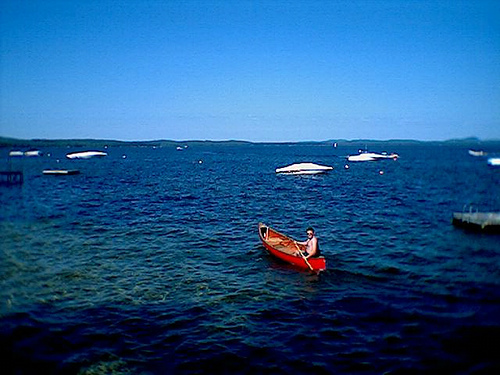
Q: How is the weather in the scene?
A: It is clear.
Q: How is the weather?
A: It is clear.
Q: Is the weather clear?
A: Yes, it is clear.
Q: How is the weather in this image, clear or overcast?
A: It is clear.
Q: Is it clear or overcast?
A: It is clear.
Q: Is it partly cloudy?
A: No, it is clear.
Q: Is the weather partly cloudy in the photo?
A: No, it is clear.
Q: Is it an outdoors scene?
A: Yes, it is outdoors.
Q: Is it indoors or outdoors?
A: It is outdoors.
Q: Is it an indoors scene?
A: No, it is outdoors.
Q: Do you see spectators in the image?
A: No, there are no spectators.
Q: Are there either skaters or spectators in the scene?
A: No, there are no spectators or skaters.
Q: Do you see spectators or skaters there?
A: No, there are no spectators or skaters.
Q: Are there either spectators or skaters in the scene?
A: No, there are no spectators or skaters.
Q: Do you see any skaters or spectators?
A: No, there are no spectators or skaters.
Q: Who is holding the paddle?
A: The man is holding the paddle.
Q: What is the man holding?
A: The man is holding the oar.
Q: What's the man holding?
A: The man is holding the oar.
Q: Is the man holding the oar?
A: Yes, the man is holding the oar.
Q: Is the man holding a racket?
A: No, the man is holding the oar.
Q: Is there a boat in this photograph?
A: Yes, there is a boat.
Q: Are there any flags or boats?
A: Yes, there is a boat.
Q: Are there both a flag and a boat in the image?
A: No, there is a boat but no flags.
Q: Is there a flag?
A: No, there are no flags.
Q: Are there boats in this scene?
A: Yes, there is a boat.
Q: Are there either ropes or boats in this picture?
A: Yes, there is a boat.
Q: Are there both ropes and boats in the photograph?
A: No, there is a boat but no ropes.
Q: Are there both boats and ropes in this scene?
A: No, there is a boat but no ropes.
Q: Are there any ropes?
A: No, there are no ropes.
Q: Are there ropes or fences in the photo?
A: No, there are no ropes or fences.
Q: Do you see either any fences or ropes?
A: No, there are no ropes or fences.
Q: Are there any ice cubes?
A: No, there are no ice cubes.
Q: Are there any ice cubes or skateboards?
A: No, there are no ice cubes or skateboards.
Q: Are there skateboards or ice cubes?
A: No, there are no ice cubes or skateboards.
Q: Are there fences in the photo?
A: No, there are no fences.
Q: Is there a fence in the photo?
A: No, there are no fences.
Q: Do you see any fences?
A: No, there are no fences.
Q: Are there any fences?
A: No, there are no fences.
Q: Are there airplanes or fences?
A: No, there are no fences or airplanes.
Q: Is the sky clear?
A: Yes, the sky is clear.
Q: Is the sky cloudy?
A: No, the sky is clear.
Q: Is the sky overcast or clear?
A: The sky is clear.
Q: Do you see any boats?
A: Yes, there is a boat.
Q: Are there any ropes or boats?
A: Yes, there is a boat.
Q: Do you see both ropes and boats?
A: No, there is a boat but no ropes.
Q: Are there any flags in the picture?
A: No, there are no flags.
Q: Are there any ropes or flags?
A: No, there are no flags or ropes.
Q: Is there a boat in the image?
A: Yes, there is a boat.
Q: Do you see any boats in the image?
A: Yes, there is a boat.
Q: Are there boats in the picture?
A: Yes, there is a boat.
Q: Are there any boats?
A: Yes, there is a boat.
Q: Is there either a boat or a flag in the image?
A: Yes, there is a boat.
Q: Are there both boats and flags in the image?
A: No, there is a boat but no flags.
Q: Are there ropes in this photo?
A: No, there are no ropes.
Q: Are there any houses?
A: No, there are no houses.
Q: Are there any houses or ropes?
A: No, there are no houses or ropes.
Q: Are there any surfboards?
A: No, there are no surfboards.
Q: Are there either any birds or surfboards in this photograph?
A: No, there are no surfboards or birds.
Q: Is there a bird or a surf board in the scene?
A: No, there are no surfboards or birds.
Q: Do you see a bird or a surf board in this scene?
A: No, there are no surfboards or birds.